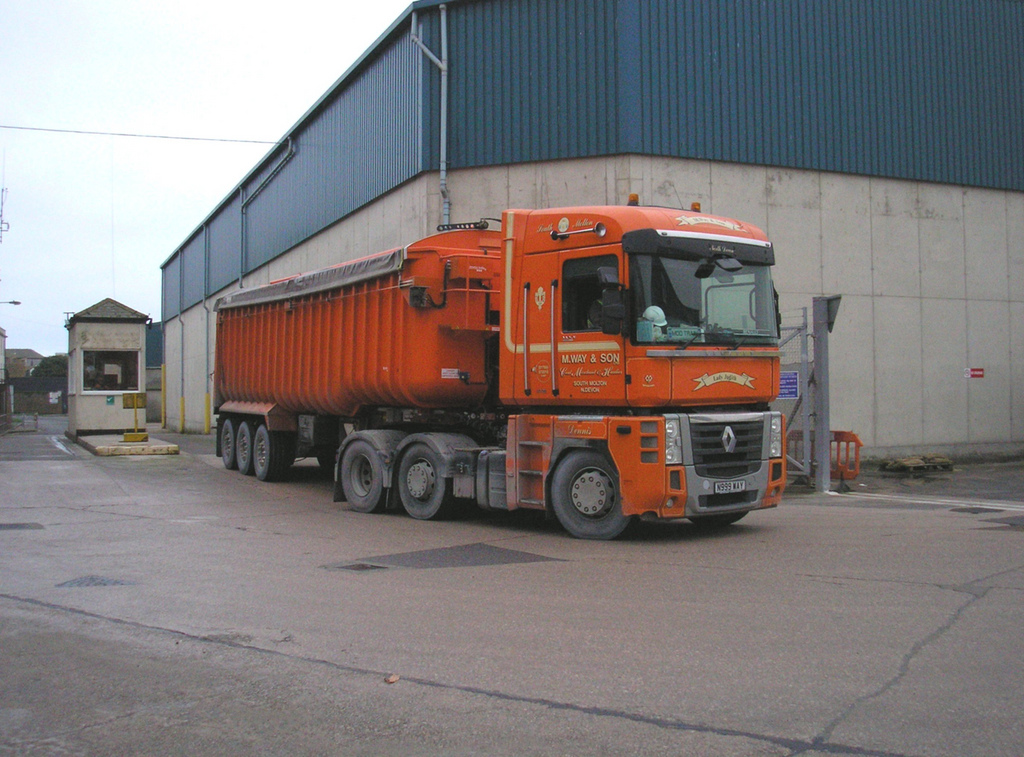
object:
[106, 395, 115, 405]
sign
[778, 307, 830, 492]
gate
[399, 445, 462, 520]
tire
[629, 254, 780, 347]
window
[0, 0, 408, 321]
cloud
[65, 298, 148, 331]
roof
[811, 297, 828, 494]
fence pole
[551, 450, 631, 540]
tire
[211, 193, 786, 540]
truck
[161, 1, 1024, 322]
roof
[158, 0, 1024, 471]
warehouse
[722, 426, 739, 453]
logo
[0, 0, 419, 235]
sky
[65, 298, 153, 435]
building